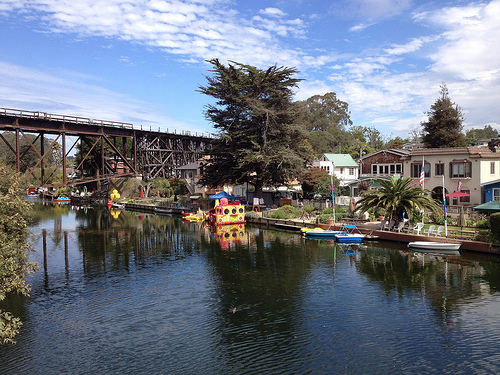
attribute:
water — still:
[3, 196, 499, 375]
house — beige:
[399, 144, 499, 229]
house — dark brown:
[357, 147, 408, 189]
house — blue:
[479, 176, 499, 205]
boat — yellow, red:
[207, 202, 249, 228]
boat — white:
[407, 237, 463, 252]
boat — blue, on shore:
[304, 227, 348, 241]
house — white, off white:
[313, 153, 360, 190]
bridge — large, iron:
[2, 107, 223, 192]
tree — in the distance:
[423, 81, 467, 150]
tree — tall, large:
[195, 54, 310, 198]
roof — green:
[322, 150, 364, 169]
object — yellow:
[109, 189, 126, 203]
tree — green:
[1, 169, 44, 344]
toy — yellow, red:
[204, 197, 249, 230]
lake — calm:
[1, 196, 499, 374]